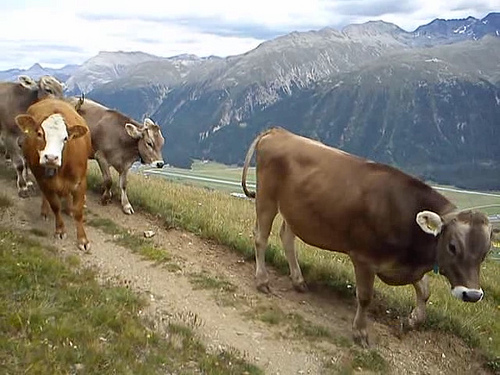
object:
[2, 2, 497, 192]
mountain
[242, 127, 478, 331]
cow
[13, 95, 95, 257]
cow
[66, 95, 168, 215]
cow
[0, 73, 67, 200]
cow